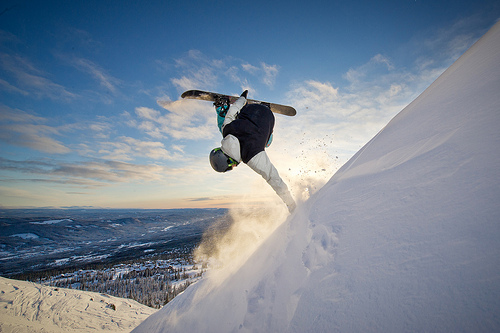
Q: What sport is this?
A: Snowboarding.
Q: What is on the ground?
A: Snow.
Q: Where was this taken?
A: Mountain.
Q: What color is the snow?
A: White.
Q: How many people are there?
A: 1.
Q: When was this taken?
A: Winter.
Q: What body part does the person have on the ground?
A: Hand.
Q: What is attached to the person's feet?
A: Snowboard.